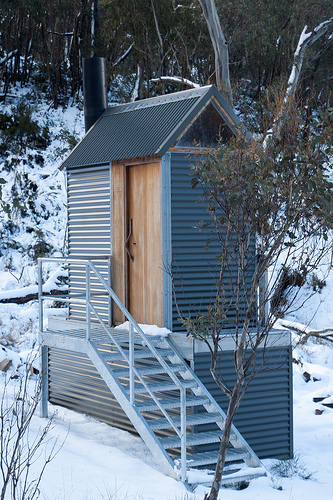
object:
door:
[124, 161, 164, 328]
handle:
[124, 219, 134, 265]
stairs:
[84, 332, 285, 493]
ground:
[0, 363, 332, 500]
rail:
[37, 252, 187, 474]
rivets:
[104, 91, 199, 115]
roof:
[57, 83, 214, 170]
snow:
[51, 408, 157, 500]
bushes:
[0, 339, 63, 500]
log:
[0, 280, 69, 304]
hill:
[0, 68, 80, 416]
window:
[175, 98, 248, 148]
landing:
[43, 319, 163, 344]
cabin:
[59, 82, 258, 328]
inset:
[112, 161, 128, 329]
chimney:
[81, 53, 108, 134]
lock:
[130, 240, 138, 249]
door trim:
[123, 163, 127, 324]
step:
[177, 464, 273, 490]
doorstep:
[112, 319, 174, 335]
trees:
[0, 0, 332, 109]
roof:
[56, 84, 257, 170]